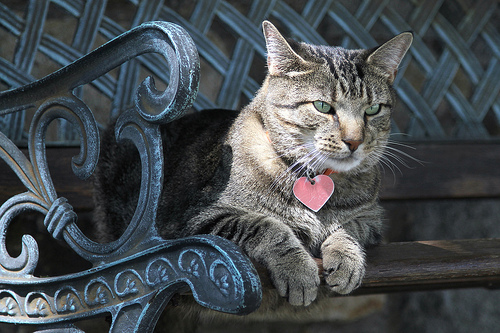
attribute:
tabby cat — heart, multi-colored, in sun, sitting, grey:
[90, 20, 431, 306]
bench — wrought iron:
[1, 1, 499, 333]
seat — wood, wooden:
[1, 140, 499, 296]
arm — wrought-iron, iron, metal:
[0, 21, 263, 325]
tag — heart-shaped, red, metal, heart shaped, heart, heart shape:
[292, 173, 336, 212]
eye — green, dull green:
[313, 100, 334, 114]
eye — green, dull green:
[365, 102, 381, 116]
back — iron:
[1, 1, 497, 149]